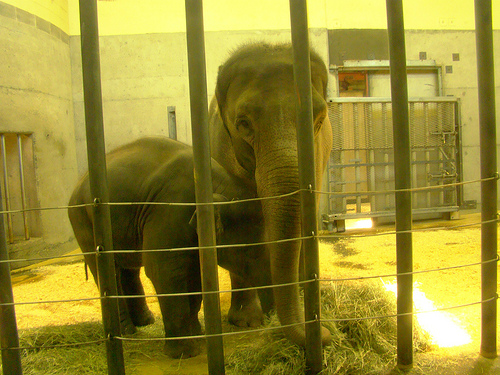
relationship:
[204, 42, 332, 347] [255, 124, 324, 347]
elephant has trunk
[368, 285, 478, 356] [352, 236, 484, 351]
light off of ground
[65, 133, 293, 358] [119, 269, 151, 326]
elephant has leg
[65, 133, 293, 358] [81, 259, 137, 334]
elephant has leg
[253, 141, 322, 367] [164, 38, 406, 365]
trunk of elephant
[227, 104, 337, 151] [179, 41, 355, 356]
eyes of elephant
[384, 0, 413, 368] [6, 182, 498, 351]
bar with wire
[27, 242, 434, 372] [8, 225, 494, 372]
straw on floor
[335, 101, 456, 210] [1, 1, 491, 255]
fence in back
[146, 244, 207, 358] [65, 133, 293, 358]
leg of elephant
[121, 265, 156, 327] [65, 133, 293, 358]
leg of elephant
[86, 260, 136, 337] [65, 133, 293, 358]
leg of elephant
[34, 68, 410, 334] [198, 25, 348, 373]
elephant standing next to elephant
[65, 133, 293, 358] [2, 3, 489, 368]
elephant in cage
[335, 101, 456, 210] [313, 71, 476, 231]
fence of cage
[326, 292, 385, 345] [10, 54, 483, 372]
hay inside cage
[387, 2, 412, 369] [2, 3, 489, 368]
bar of cage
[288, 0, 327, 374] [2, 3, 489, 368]
bar on cage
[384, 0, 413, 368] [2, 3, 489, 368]
bar on cage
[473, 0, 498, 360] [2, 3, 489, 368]
bar on cage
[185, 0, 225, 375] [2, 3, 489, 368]
bar on cage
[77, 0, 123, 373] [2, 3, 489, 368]
bar on cage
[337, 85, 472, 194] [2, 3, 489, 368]
fence on cage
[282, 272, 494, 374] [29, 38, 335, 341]
greengrass under elephants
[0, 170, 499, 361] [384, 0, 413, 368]
wires on bar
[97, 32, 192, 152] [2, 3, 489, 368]
walls in cage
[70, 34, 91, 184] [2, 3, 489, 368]
walls in cage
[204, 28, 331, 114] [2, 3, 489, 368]
walls in cage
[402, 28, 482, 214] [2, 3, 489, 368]
walls in cage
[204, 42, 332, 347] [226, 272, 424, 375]
elephant standing on greengrass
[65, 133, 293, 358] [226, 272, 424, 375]
elephant standing on greengrass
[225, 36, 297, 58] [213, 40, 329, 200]
hairs on head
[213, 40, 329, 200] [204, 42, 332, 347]
head of elephant